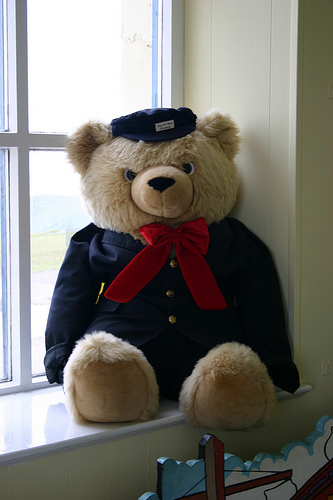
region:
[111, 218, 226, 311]
The bow is red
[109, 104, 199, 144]
The hat is blue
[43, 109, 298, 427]
The teddy bear is brown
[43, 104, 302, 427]
The teddy bear is on the window sill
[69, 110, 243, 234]
The bear is wearing a hat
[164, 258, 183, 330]
Gold buttons on the jacket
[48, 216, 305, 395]
The jacket is blue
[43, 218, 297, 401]
The bear is wearing a jacket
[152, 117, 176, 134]
White patch on front of hat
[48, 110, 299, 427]
The teddy bear is propped against the window sill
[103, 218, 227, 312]
A red ribbon bow.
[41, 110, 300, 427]
A tan teddy bear.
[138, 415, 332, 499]
A painted piece of wood.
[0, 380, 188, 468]
A white window sill.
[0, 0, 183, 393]
A white framed window.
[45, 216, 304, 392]
A dark blue jacket.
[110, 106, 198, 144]
A navy blue hat.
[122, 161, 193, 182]
A set of toy bear eyes.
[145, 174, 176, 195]
A black teddy bear nose.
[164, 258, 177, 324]
A set of gold buttons.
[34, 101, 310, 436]
teddy bear wearing a navy outfit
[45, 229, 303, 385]
navy jacket teddy bear is wearing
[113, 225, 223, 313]
red bow on bear's neck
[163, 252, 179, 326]
three gold buttons on navy coat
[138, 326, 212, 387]
blue shorts bear is wearing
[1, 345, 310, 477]
white window ledge bear is sitting on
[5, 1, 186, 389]
white frame of the window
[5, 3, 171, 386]
window bear is sitting beside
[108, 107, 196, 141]
navy cap of the bear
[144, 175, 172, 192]
black nose of the bear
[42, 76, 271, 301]
a teddy bear in a window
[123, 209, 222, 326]
a red bow on the bear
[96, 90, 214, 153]
a blue hat on the bear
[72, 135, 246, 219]
the teddy bear is tan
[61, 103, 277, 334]
this teddy bear looks like a flight attendant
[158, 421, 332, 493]
some kind of display beneath the bear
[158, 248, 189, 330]
buttons on the blue jacket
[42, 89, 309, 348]
the teddy bear is in the corner of the window seal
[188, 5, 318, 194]
a white wall behind the bear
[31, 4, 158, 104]
hazy light is shining through the window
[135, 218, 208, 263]
red bow on bear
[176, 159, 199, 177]
left eye on bear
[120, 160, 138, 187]
right eye on bear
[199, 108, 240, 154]
left ear on bear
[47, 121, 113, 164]
right ear on bear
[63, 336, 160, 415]
right foot on bear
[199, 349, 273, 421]
left foot on bear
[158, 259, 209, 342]
gold buttons on jacket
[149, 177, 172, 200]
black nose on bear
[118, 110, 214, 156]
blue hat on bear